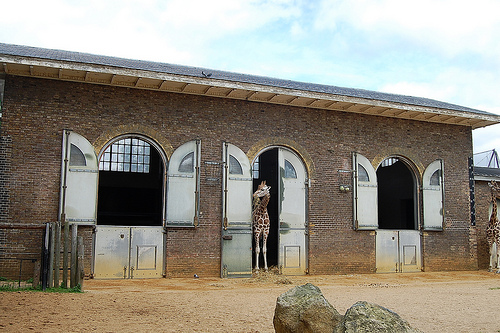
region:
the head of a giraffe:
[240, 177, 277, 208]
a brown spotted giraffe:
[241, 168, 286, 235]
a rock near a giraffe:
[257, 248, 438, 328]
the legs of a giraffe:
[245, 212, 291, 263]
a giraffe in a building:
[140, 58, 441, 294]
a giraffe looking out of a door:
[205, 128, 362, 272]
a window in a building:
[85, 132, 167, 189]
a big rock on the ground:
[261, 265, 448, 326]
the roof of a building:
[179, 56, 426, 108]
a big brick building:
[54, 48, 396, 225]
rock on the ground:
[335, 293, 419, 327]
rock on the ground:
[272, 272, 342, 329]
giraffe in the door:
[251, 181, 276, 279]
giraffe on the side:
[485, 178, 497, 272]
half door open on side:
[168, 136, 201, 230]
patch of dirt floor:
[123, 310, 148, 326]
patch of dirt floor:
[445, 296, 462, 309]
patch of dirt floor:
[167, 293, 183, 304]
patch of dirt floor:
[76, 304, 96, 324]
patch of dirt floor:
[153, 275, 179, 290]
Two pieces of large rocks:
[265, 278, 414, 331]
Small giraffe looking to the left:
[236, 168, 293, 275]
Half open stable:
[347, 131, 469, 275]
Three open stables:
[50, 96, 467, 286]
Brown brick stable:
[2, 37, 494, 285]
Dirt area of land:
[1, 283, 498, 332]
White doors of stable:
[344, 138, 459, 283]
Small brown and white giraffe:
[239, 176, 291, 274]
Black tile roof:
[0, 36, 498, 138]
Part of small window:
[93, 130, 154, 181]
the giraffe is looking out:
[229, 160, 289, 277]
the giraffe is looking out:
[213, 135, 333, 327]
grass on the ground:
[14, 275, 97, 297]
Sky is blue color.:
[291, 26, 361, 79]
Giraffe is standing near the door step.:
[235, 172, 292, 282]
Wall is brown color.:
[11, 109, 56, 191]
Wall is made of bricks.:
[13, 98, 50, 201]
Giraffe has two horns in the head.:
[253, 175, 275, 194]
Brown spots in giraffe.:
[247, 187, 286, 249]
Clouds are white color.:
[113, 18, 186, 55]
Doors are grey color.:
[58, 125, 463, 275]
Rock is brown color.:
[261, 289, 373, 331]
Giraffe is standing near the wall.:
[476, 166, 499, 276]